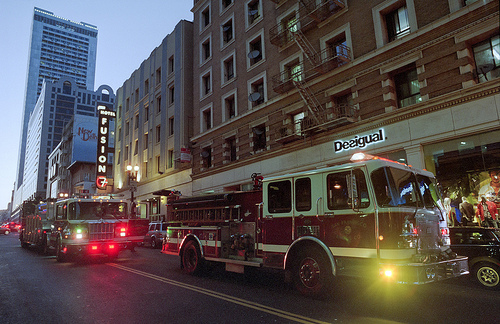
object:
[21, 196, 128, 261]
firetruck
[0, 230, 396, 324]
street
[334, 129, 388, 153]
sign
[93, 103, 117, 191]
text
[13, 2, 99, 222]
building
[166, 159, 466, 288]
truck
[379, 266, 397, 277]
light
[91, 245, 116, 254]
light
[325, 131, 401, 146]
text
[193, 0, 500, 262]
building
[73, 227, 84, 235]
light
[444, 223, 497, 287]
vehicle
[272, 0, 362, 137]
stairs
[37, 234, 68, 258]
wheels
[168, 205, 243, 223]
ladder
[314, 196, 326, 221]
doorhandle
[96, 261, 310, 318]
divider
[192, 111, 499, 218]
store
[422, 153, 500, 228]
window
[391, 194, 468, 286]
headlights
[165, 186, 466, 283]
side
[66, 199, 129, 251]
front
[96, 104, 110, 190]
fusion7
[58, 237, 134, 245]
bumper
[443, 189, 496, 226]
mannequins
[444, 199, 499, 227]
clothing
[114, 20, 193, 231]
building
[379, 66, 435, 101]
windows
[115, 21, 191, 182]
stripes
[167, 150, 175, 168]
windows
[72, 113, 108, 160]
advertisement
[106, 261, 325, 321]
stripe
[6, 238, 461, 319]
road